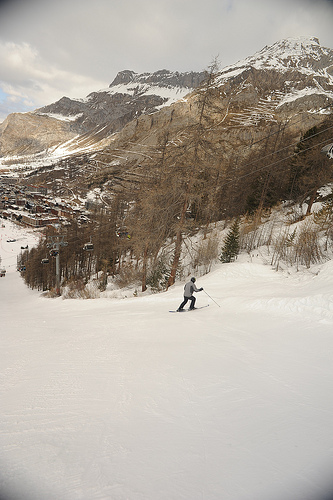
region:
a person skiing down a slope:
[180, 276, 203, 316]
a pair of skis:
[171, 302, 211, 312]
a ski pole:
[201, 286, 222, 309]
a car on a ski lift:
[80, 239, 96, 251]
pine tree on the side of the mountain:
[221, 214, 242, 263]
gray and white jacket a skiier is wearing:
[183, 282, 201, 298]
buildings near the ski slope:
[1, 185, 79, 228]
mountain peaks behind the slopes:
[51, 38, 331, 175]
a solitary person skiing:
[171, 276, 214, 312]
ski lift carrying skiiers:
[1, 227, 158, 256]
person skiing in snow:
[165, 271, 223, 315]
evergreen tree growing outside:
[217, 215, 242, 266]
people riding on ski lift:
[17, 265, 28, 273]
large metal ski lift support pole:
[47, 233, 70, 297]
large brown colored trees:
[244, 127, 332, 234]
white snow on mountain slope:
[43, 129, 119, 159]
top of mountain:
[259, 35, 332, 81]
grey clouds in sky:
[1, 3, 331, 92]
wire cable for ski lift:
[141, 99, 332, 187]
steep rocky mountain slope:
[148, 62, 226, 120]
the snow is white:
[49, 322, 220, 469]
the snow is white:
[73, 411, 130, 461]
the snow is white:
[81, 389, 130, 445]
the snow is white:
[73, 381, 169, 464]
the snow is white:
[95, 352, 197, 492]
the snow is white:
[148, 414, 209, 486]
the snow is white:
[118, 402, 179, 497]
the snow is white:
[97, 394, 162, 485]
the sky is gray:
[24, 6, 233, 48]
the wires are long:
[180, 137, 314, 201]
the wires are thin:
[226, 156, 274, 177]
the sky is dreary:
[46, 12, 231, 44]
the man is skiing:
[171, 276, 214, 318]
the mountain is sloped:
[174, 34, 321, 91]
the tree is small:
[219, 219, 248, 267]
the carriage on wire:
[82, 235, 95, 253]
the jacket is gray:
[177, 281, 197, 294]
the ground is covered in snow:
[22, 328, 275, 464]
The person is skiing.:
[162, 268, 215, 322]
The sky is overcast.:
[0, 0, 93, 115]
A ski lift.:
[3, 208, 133, 274]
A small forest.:
[39, 152, 313, 279]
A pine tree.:
[217, 213, 241, 264]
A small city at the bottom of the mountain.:
[0, 174, 110, 237]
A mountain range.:
[6, 58, 198, 126]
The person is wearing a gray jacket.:
[173, 276, 197, 296]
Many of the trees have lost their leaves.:
[124, 168, 237, 256]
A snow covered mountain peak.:
[251, 31, 328, 82]